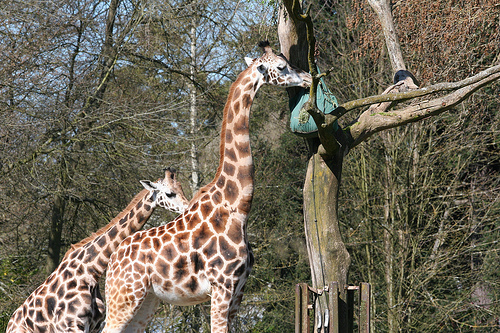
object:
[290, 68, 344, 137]
blue bag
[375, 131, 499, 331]
bare branches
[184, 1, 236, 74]
blue skies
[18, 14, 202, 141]
tree branches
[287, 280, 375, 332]
fence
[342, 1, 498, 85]
leaves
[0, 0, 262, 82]
sky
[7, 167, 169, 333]
giraffe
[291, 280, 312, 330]
posts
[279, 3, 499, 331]
tree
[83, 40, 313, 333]
giraffe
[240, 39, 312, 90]
head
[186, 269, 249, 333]
legs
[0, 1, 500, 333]
trees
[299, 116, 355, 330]
moss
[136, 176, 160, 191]
ear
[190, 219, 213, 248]
spot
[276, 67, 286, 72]
eye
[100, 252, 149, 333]
leg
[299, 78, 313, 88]
mouth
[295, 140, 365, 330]
tree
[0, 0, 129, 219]
tree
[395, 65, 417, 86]
object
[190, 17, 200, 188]
tree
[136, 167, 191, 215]
head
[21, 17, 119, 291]
tree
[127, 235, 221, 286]
skin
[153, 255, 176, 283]
spots